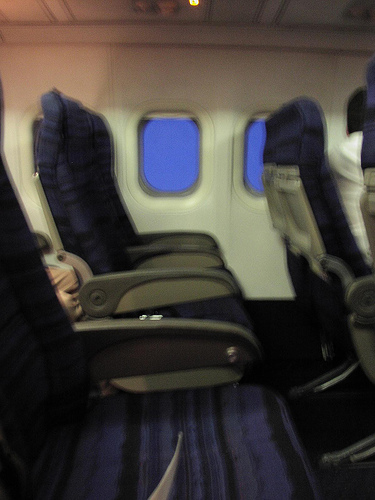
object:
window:
[138, 111, 203, 196]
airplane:
[0, 0, 373, 499]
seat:
[26, 87, 255, 329]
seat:
[0, 149, 321, 500]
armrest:
[80, 262, 242, 320]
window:
[240, 116, 272, 196]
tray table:
[273, 167, 330, 279]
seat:
[262, 95, 366, 372]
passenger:
[326, 86, 374, 272]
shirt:
[328, 131, 371, 269]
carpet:
[94, 385, 285, 498]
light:
[187, 0, 201, 8]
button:
[223, 346, 241, 367]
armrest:
[70, 320, 264, 382]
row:
[33, 157, 350, 195]